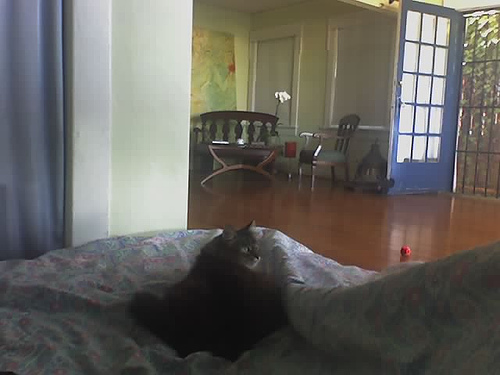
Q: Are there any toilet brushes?
A: No, there are no toilet brushes.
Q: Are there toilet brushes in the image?
A: No, there are no toilet brushes.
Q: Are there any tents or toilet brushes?
A: No, there are no toilet brushes or tents.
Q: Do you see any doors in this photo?
A: Yes, there is a door.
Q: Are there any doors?
A: Yes, there is a door.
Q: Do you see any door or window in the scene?
A: Yes, there is a door.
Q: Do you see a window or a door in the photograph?
A: Yes, there is a door.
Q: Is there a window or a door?
A: Yes, there is a door.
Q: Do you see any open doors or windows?
A: Yes, there is an open door.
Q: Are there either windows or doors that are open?
A: Yes, the door is open.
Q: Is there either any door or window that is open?
A: Yes, the door is open.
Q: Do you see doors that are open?
A: Yes, there is an open door.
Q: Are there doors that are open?
A: Yes, there is a door that is open.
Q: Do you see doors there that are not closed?
A: Yes, there is a open door.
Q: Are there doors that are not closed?
A: Yes, there is a open door.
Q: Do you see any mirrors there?
A: No, there are no mirrors.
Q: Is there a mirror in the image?
A: No, there are no mirrors.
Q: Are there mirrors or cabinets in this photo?
A: No, there are no mirrors or cabinets.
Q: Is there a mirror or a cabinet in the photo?
A: No, there are no mirrors or cabinets.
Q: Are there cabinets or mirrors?
A: No, there are no mirrors or cabinets.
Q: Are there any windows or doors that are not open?
A: No, there is a door but it is open.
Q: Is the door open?
A: Yes, the door is open.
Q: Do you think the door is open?
A: Yes, the door is open.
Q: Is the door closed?
A: No, the door is open.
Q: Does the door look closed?
A: No, the door is open.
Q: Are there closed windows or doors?
A: No, there is a door but it is open.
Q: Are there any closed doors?
A: No, there is a door but it is open.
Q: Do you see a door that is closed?
A: No, there is a door but it is open.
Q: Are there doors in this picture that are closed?
A: No, there is a door but it is open.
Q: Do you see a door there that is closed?
A: No, there is a door but it is open.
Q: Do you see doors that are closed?
A: No, there is a door but it is open.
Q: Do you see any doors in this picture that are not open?
A: No, there is a door but it is open.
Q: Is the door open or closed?
A: The door is open.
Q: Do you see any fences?
A: No, there are no fences.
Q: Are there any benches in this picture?
A: Yes, there is a bench.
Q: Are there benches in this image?
A: Yes, there is a bench.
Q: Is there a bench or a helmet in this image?
A: Yes, there is a bench.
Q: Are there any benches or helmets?
A: Yes, there is a bench.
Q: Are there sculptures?
A: No, there are no sculptures.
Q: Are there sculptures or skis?
A: No, there are no sculptures or skis.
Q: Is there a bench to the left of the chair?
A: Yes, there is a bench to the left of the chair.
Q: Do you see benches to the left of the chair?
A: Yes, there is a bench to the left of the chair.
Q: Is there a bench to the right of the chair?
A: No, the bench is to the left of the chair.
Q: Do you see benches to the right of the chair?
A: No, the bench is to the left of the chair.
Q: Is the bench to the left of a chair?
A: Yes, the bench is to the left of a chair.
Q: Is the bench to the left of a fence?
A: No, the bench is to the left of a chair.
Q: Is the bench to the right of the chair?
A: No, the bench is to the left of the chair.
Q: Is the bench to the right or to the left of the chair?
A: The bench is to the left of the chair.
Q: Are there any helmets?
A: No, there are no helmets.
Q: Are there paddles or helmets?
A: No, there are no helmets or paddles.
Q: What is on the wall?
A: The painting is on the wall.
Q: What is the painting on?
A: The painting is on the wall.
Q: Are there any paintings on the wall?
A: Yes, there is a painting on the wall.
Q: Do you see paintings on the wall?
A: Yes, there is a painting on the wall.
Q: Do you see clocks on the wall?
A: No, there is a painting on the wall.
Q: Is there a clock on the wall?
A: No, there is a painting on the wall.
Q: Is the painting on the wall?
A: Yes, the painting is on the wall.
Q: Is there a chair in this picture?
A: Yes, there is a chair.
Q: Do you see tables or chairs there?
A: Yes, there is a chair.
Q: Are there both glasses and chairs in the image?
A: No, there is a chair but no glasses.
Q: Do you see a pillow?
A: No, there are no pillows.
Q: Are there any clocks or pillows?
A: No, there are no pillows or clocks.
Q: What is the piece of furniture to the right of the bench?
A: The piece of furniture is a chair.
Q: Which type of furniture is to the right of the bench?
A: The piece of furniture is a chair.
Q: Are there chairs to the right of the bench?
A: Yes, there is a chair to the right of the bench.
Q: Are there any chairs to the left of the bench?
A: No, the chair is to the right of the bench.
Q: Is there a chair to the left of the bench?
A: No, the chair is to the right of the bench.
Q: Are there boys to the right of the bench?
A: No, there is a chair to the right of the bench.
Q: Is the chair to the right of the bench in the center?
A: Yes, the chair is to the right of the bench.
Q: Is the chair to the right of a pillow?
A: No, the chair is to the right of the bench.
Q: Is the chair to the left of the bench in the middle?
A: No, the chair is to the right of the bench.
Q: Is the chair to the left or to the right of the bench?
A: The chair is to the right of the bench.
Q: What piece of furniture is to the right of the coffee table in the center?
A: The piece of furniture is a chair.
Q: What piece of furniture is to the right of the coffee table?
A: The piece of furniture is a chair.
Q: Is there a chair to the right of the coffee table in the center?
A: Yes, there is a chair to the right of the coffee table.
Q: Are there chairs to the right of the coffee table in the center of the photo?
A: Yes, there is a chair to the right of the coffee table.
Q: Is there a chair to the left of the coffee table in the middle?
A: No, the chair is to the right of the coffee table.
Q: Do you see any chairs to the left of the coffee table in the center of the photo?
A: No, the chair is to the right of the coffee table.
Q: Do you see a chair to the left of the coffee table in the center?
A: No, the chair is to the right of the coffee table.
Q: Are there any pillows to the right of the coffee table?
A: No, there is a chair to the right of the coffee table.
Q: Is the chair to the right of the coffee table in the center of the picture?
A: Yes, the chair is to the right of the coffee table.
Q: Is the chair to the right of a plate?
A: No, the chair is to the right of the coffee table.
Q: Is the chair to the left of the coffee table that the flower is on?
A: No, the chair is to the right of the coffee table.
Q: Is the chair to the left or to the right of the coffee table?
A: The chair is to the right of the coffee table.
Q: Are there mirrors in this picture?
A: No, there are no mirrors.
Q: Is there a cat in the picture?
A: Yes, there is a cat.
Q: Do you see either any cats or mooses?
A: Yes, there is a cat.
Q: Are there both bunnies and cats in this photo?
A: No, there is a cat but no bunnies.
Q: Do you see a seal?
A: No, there are no seals.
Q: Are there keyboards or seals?
A: No, there are no seals or keyboards.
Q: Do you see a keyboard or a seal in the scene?
A: No, there are no seals or keyboards.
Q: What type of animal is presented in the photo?
A: The animal is a cat.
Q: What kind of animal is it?
A: The animal is a cat.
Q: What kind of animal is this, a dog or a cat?
A: This is a cat.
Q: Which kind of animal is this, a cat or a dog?
A: This is a cat.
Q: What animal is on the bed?
A: The cat is on the bed.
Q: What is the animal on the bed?
A: The animal is a cat.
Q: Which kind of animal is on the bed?
A: The animal is a cat.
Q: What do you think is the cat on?
A: The cat is on the bed.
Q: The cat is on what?
A: The cat is on the bed.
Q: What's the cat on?
A: The cat is on the bed.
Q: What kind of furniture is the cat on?
A: The cat is on the bed.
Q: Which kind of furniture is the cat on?
A: The cat is on the bed.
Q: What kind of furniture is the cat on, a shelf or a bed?
A: The cat is on a bed.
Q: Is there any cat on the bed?
A: Yes, there is a cat on the bed.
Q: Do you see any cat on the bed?
A: Yes, there is a cat on the bed.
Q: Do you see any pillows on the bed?
A: No, there is a cat on the bed.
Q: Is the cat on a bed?
A: Yes, the cat is on a bed.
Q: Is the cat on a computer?
A: No, the cat is on a bed.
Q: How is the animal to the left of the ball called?
A: The animal is a cat.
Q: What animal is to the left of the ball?
A: The animal is a cat.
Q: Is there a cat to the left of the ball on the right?
A: Yes, there is a cat to the left of the ball.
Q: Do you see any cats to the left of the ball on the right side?
A: Yes, there is a cat to the left of the ball.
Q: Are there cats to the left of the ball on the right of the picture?
A: Yes, there is a cat to the left of the ball.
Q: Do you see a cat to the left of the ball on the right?
A: Yes, there is a cat to the left of the ball.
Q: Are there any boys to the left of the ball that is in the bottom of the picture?
A: No, there is a cat to the left of the ball.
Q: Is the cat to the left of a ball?
A: Yes, the cat is to the left of a ball.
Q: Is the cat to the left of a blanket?
A: No, the cat is to the left of a ball.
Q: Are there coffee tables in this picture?
A: Yes, there is a coffee table.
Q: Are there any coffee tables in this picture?
A: Yes, there is a coffee table.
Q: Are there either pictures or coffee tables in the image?
A: Yes, there is a coffee table.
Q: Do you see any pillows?
A: No, there are no pillows.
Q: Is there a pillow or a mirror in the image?
A: No, there are no pillows or mirrors.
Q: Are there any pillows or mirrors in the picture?
A: No, there are no pillows or mirrors.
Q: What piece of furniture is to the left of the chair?
A: The piece of furniture is a coffee table.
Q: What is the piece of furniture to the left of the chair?
A: The piece of furniture is a coffee table.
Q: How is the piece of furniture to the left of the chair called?
A: The piece of furniture is a coffee table.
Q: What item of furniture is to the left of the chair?
A: The piece of furniture is a coffee table.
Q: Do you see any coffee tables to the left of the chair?
A: Yes, there is a coffee table to the left of the chair.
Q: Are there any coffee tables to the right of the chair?
A: No, the coffee table is to the left of the chair.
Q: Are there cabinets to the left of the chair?
A: No, there is a coffee table to the left of the chair.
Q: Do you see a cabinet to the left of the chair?
A: No, there is a coffee table to the left of the chair.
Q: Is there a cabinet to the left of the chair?
A: No, there is a coffee table to the left of the chair.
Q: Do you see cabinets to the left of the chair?
A: No, there is a coffee table to the left of the chair.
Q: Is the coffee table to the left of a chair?
A: Yes, the coffee table is to the left of a chair.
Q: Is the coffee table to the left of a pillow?
A: No, the coffee table is to the left of a chair.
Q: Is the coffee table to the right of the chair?
A: No, the coffee table is to the left of the chair.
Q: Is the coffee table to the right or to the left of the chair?
A: The coffee table is to the left of the chair.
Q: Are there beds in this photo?
A: Yes, there is a bed.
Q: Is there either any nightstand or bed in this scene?
A: Yes, there is a bed.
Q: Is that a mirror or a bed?
A: That is a bed.